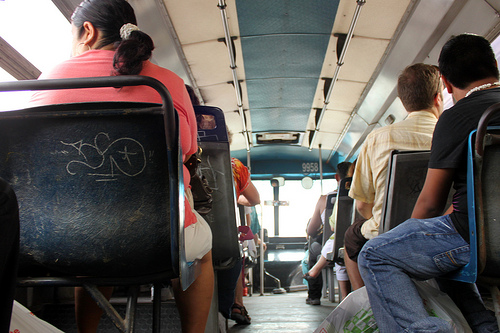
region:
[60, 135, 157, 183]
GRAFFITI ON BACK OF SEAT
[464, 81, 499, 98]
MAN IS WEARING WHITE SHELL NECKLACE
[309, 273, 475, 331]
LARGE SHOPPING BAG ON FLOOR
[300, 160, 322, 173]
9958 IN WHITE LETTERS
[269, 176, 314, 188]
TWO MIRRORS OVER WINDSHIELD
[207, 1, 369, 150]
METAL HAND RAILINGS ON ROOF OF BUS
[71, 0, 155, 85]
WOMAN'S HAIR IS IN A PONYTAIL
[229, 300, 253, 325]
BROWN SANDAL ON FOOT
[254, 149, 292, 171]
BLUE PAINT TRIM ON BUS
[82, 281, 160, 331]
METAL LEGS ON SEATS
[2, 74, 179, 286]
A seat in the photo.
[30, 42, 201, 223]
A red t-shirt in the photo.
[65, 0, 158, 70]
Black hair in the photo.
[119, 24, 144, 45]
White hair band in the photo.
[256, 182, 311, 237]
Windscreen in the photo.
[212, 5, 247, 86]
Metal bar in the bus.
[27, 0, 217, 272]
A woman in the photo.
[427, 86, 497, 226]
A black t-shirt in the photo.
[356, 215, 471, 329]
Blue jeans in the photo.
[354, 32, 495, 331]
A man in the photo.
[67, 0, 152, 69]
Long black hair in the photo.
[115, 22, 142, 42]
A white hair band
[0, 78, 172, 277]
A seat in the bus.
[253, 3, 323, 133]
Roof in the bus.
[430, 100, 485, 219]
Black t-shirt in the photo.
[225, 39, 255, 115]
Metal bar in the photo.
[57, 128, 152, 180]
graffitti on back of chair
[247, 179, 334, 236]
glare through front window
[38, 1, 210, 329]
Student sitting on bus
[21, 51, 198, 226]
pink shirt worn by bus rider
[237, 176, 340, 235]
front window of bus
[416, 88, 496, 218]
black shirt worn by bus rider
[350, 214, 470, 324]
jeans worn by bus rider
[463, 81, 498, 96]
white necklace worn by bus rider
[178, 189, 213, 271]
white short worn by bus rider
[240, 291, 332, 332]
floor of bus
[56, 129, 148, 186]
Graffiti on the back of the seat.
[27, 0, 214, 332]
A woman wearing a red shirt.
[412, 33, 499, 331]
A man wearing a black shirt.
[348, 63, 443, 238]
A man wearing a white shirt.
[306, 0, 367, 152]
Hand rails on the roof of the bus.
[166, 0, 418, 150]
The bus ceiling is white and blue.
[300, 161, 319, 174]
The bus number is 9958.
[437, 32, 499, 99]
The man has a white necklace on.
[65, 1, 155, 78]
The woman is wearing a white hair tie.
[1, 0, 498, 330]
The bus is full of people.